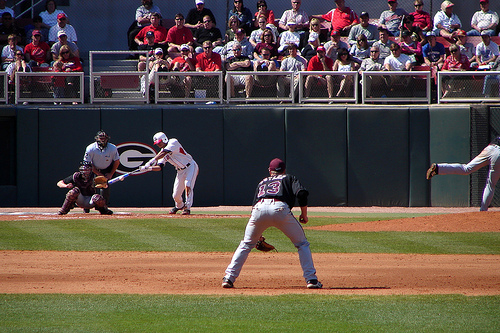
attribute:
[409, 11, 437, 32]
shirt — red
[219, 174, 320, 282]
uniform — gray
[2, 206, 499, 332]
field — green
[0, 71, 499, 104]
fence — white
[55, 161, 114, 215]
catcher — here, squatting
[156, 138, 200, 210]
uniform — white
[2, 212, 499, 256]
grass — green', green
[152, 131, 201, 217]
player — bent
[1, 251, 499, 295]
dirt — brown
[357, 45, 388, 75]
spectator — here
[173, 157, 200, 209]
pants — white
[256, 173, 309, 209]
shirt — dark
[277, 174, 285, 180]
letter — white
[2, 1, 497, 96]
crowd — here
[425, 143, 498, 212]
man — falling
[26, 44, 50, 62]
shirt — red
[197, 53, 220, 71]
shirt — red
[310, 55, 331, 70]
shirt — red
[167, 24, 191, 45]
shirt — red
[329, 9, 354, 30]
shirt — red